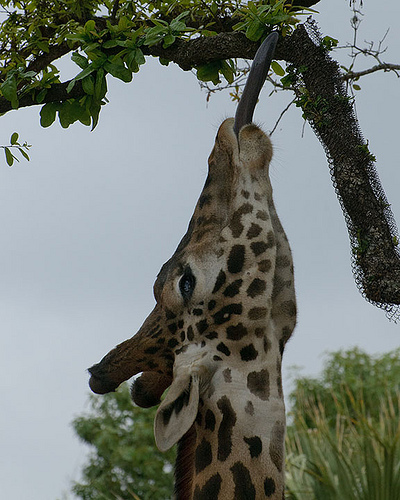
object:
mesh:
[330, 106, 374, 144]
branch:
[280, 18, 400, 314]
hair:
[171, 430, 193, 492]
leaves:
[3, 1, 30, 41]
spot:
[214, 394, 240, 466]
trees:
[283, 342, 379, 394]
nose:
[200, 142, 225, 164]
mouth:
[199, 109, 280, 175]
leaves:
[63, 99, 91, 122]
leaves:
[66, 2, 94, 40]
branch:
[7, 0, 190, 124]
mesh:
[285, 29, 330, 92]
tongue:
[218, 27, 278, 125]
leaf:
[230, 4, 307, 35]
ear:
[151, 362, 203, 457]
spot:
[238, 365, 274, 402]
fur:
[228, 347, 284, 400]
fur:
[198, 400, 290, 491]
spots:
[210, 202, 244, 234]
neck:
[160, 352, 288, 498]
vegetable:
[265, 59, 285, 88]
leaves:
[0, 48, 20, 84]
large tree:
[1, 2, 384, 324]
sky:
[3, 118, 205, 225]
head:
[82, 116, 295, 389]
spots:
[190, 211, 216, 244]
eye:
[175, 268, 197, 304]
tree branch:
[347, 202, 384, 317]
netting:
[355, 227, 384, 279]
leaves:
[0, 133, 32, 162]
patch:
[111, 107, 196, 191]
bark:
[200, 47, 246, 60]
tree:
[0, 3, 378, 101]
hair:
[253, 120, 271, 141]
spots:
[241, 428, 264, 458]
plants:
[294, 337, 387, 497]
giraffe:
[86, 25, 313, 500]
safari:
[7, 0, 398, 496]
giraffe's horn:
[90, 327, 166, 409]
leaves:
[83, 70, 109, 119]